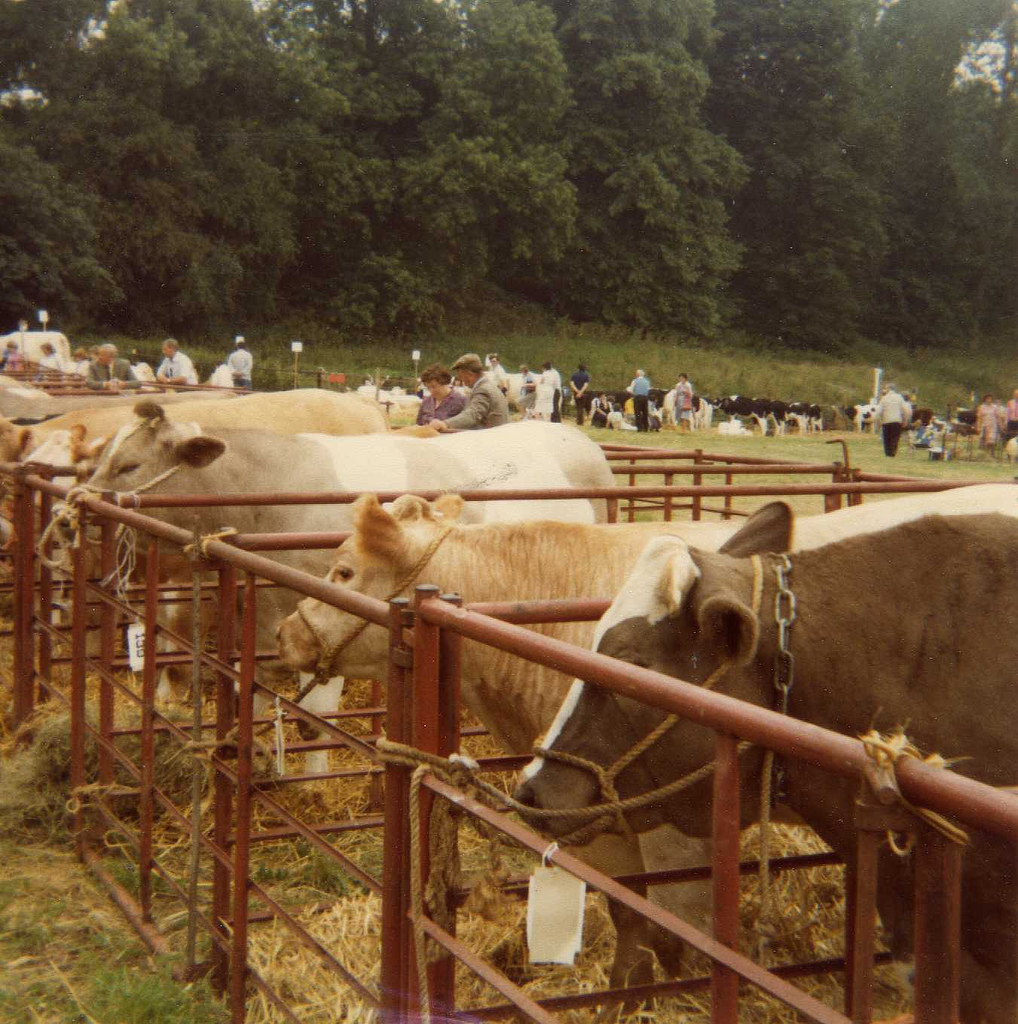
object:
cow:
[511, 477, 1017, 1021]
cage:
[379, 582, 1016, 1020]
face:
[503, 500, 805, 849]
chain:
[769, 546, 799, 811]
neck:
[742, 538, 888, 839]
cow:
[274, 488, 769, 1020]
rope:
[289, 514, 464, 705]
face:
[276, 495, 464, 680]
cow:
[36, 396, 622, 784]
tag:
[522, 860, 590, 966]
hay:
[102, 667, 783, 1020]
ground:
[0, 346, 1018, 1018]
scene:
[3, 0, 1018, 1021]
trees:
[0, 138, 133, 330]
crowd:
[0, 302, 1017, 457]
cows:
[705, 388, 774, 439]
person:
[628, 365, 653, 434]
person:
[671, 371, 698, 435]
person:
[568, 359, 594, 424]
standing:
[0, 271, 1018, 576]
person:
[872, 386, 914, 457]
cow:
[700, 388, 785, 439]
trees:
[551, 0, 752, 348]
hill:
[608, 331, 769, 389]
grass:
[594, 234, 689, 298]